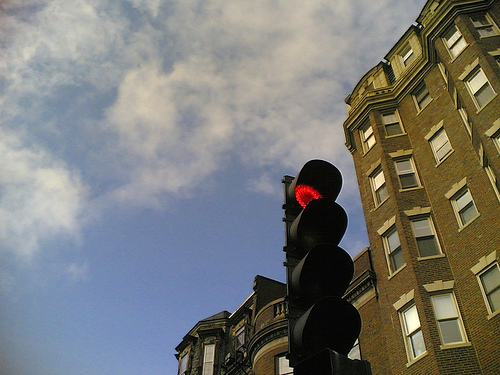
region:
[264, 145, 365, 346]
red signal light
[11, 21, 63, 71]
white clouds in blue sky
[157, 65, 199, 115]
white clouds in blue sky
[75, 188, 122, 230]
white clouds in blue sky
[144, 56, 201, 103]
white clouds in blue sky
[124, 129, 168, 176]
white clouds in blue sky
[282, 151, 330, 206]
red light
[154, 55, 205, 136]
white clouds in blue sky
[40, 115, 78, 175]
white clouds in blue sky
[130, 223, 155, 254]
white clouds in blue sky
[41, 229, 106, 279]
white clouds in blue sky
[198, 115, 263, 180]
white clouds in blue sky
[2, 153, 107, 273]
white clouds in blue sky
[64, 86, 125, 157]
white clouds in blue sky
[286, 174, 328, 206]
red light of the stoplight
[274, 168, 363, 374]
black stoplight on a post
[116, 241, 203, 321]
clear blue skies over the building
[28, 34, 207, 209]
sparse white clouds in the sky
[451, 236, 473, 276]
brown brick wall of the building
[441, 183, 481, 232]
white concrete trim of the window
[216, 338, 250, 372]
black metal fence of the fire escape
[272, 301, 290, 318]
tan concrete posts of the balcony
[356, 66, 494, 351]
many windows on the side of the building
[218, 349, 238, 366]
metal air conditioner in the window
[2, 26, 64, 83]
white clouds in blue sky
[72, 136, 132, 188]
white clouds in blue sky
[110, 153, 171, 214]
white clouds in blue sky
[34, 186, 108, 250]
white clouds in blue sky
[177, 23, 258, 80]
white clouds in blue sky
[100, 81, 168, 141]
white clouds in blue sky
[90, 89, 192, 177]
white clouds in blue sky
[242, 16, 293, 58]
white clouds in blue sky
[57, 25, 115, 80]
white clouds in blue sky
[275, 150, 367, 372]
a traffic light is in red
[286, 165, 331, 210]
the light is red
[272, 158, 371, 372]
traffic light on pole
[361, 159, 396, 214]
a window with tan frame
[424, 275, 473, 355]
a window with tan frame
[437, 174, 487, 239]
a window with tan frame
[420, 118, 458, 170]
a window with tan frame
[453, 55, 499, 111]
a window with tan frame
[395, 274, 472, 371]
windows has curtains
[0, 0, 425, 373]
A sky full of clouds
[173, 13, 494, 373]
A large brick building with many windows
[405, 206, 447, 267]
A closed window with a brown decoration above it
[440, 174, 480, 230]
A closed window with a brown decoration above it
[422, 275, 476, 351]
A closed window with a brown decoration above it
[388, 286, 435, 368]
A closed window with a brown decoration above it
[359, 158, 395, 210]
A closed window with a brown decoration above it